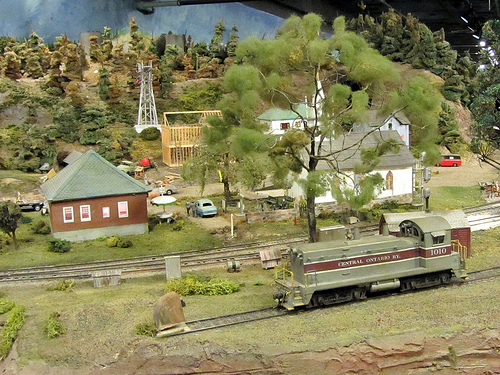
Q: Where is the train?
A: Behind the buildings.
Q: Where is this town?
A: By the train tracks.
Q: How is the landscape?
A: Flat.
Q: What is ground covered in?
A: Brown and green grass.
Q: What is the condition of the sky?
A: Blue and cloudy.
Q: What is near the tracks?
A: A brown house.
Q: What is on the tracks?
A: A train with no boxcars.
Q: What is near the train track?
A: A large tree.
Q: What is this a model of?
A: A small town and train.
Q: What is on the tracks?
A: A train.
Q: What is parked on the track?
A: A train.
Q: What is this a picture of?
A: A model town.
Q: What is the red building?
A: A home.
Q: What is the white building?
A: A church.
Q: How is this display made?
A: With model train sets.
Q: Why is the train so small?
A: It is a model.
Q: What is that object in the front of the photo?
A: A model train.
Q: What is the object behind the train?
A: A tree.